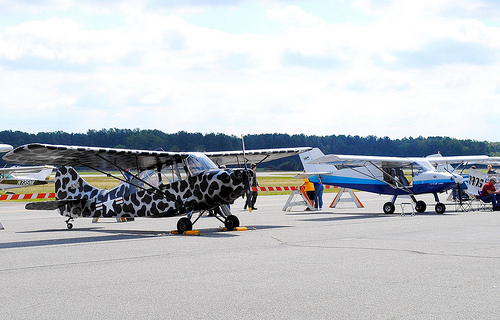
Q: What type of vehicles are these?
A: Airplanes.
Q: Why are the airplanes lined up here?
A: For the air show.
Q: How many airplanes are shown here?
A: Three.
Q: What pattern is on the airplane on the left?
A: Leopard print.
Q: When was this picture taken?
A: Daytime.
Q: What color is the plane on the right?
A: White and blue.